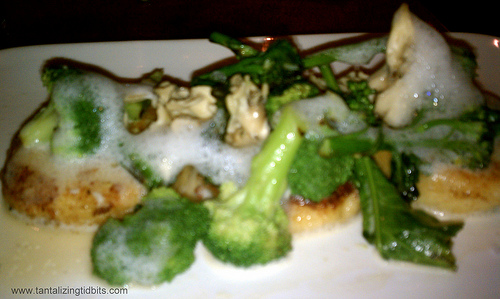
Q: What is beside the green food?
A: White chunks.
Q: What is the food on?
A: White plate.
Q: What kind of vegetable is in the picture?
A: Broccoli.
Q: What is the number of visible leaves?
A: One.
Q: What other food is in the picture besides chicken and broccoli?
A: Mushrooms.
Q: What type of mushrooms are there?
A: White Button mushrooms.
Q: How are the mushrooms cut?
A: In slices.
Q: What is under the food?
A: A white plate.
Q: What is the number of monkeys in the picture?
A: Zero.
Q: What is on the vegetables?
A: White foam.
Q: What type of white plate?
A: A piece of white plate.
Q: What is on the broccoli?
A: Soap bubbles on it.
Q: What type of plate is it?
A: A white plate.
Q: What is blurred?
A: The food.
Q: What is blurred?
A: The food.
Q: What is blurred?
A: The food.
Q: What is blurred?
A: The food.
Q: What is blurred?
A: The food.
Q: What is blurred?
A: The food.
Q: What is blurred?
A: The food.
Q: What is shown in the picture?
A: A piece of broccoli.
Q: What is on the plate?
A: A cooked leaf.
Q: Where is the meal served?
A: Dining room.